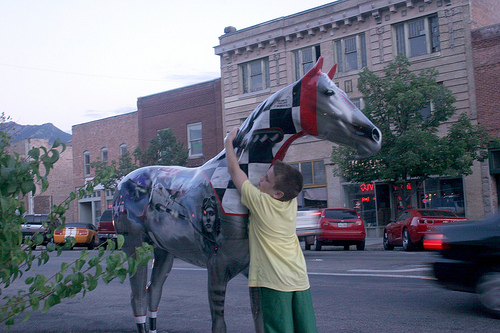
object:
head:
[291, 54, 384, 162]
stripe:
[298, 65, 316, 138]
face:
[307, 70, 382, 157]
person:
[200, 127, 320, 333]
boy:
[222, 128, 314, 331]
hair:
[271, 156, 305, 204]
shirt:
[238, 180, 311, 293]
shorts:
[258, 286, 319, 333]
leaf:
[114, 232, 127, 249]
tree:
[2, 113, 158, 332]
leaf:
[96, 244, 107, 262]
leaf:
[50, 147, 61, 167]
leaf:
[41, 174, 50, 197]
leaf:
[18, 180, 34, 198]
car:
[382, 206, 468, 251]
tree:
[330, 60, 490, 213]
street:
[0, 241, 499, 333]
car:
[51, 223, 100, 251]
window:
[331, 30, 370, 79]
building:
[0, 0, 500, 255]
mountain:
[1, 120, 73, 151]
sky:
[0, 1, 335, 135]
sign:
[358, 182, 376, 194]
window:
[349, 182, 390, 229]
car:
[17, 214, 56, 251]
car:
[417, 213, 499, 314]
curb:
[310, 240, 390, 252]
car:
[313, 206, 368, 252]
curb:
[11, 239, 117, 251]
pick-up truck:
[290, 208, 322, 251]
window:
[388, 8, 443, 65]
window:
[236, 56, 273, 97]